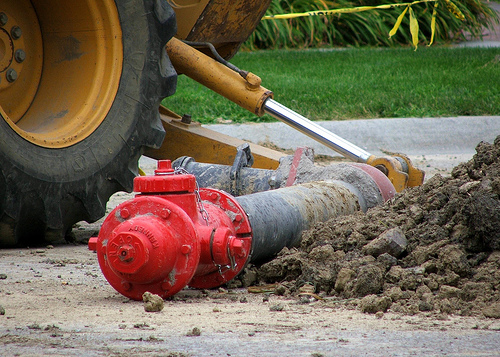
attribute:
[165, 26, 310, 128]
paint — yellow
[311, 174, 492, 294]
dirt — brown, piled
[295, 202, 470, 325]
dirt — piled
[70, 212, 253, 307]
rocks — small 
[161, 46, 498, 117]
lawn — small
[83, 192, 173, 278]
cap — red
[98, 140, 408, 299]
pipe — dirty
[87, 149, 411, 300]
pipe — metal, grey 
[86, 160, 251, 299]
hydrant — red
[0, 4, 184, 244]
wheel — huge 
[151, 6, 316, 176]
crane — yellow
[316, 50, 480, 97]
luscious grass — luscious , green 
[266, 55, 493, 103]
green grass — green , luscious  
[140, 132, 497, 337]
rocks — chunks 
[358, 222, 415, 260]
clump — large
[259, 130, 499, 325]
dirt — piled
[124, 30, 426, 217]
brace — metal, yellow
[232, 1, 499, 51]
fern leaves — yellow, green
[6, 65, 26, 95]
lug nut — large, gray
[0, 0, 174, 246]
tire — black, yellow, thick, large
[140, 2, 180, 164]
grooves — large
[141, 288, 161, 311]
clump — small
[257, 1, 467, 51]
tape — yellow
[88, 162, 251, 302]
cap — bright red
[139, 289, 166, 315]
clump — small